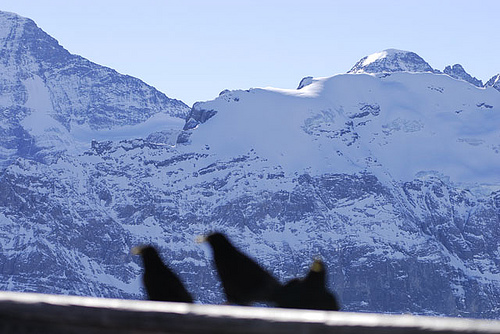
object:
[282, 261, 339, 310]
animal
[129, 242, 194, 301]
animal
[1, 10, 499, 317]
field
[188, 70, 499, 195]
snow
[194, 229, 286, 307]
animal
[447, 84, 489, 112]
snow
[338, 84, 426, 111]
snow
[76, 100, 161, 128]
snow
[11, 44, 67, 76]
snow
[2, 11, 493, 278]
mountain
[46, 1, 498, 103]
sky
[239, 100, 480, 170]
ice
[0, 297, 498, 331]
field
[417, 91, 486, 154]
view